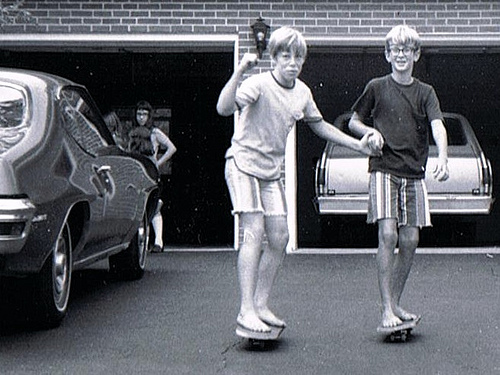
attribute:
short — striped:
[222, 150, 289, 218]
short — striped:
[364, 154, 432, 222]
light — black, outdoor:
[248, 10, 275, 64]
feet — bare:
[377, 294, 423, 327]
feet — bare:
[237, 300, 290, 335]